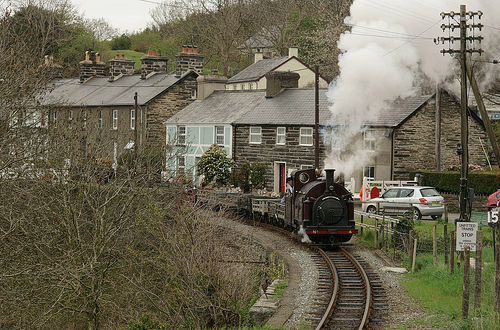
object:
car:
[361, 177, 449, 225]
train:
[237, 157, 362, 247]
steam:
[332, 1, 497, 161]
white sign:
[455, 219, 479, 255]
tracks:
[307, 246, 387, 328]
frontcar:
[283, 168, 360, 242]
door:
[268, 160, 290, 192]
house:
[168, 50, 498, 247]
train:
[178, 154, 373, 274]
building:
[235, 22, 362, 61]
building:
[221, 47, 328, 93]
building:
[9, 43, 218, 178]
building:
[160, 69, 272, 190]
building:
[230, 67, 491, 194]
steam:
[323, 0, 492, 181]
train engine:
[284, 165, 358, 248]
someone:
[283, 174, 299, 231]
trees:
[15, 53, 195, 310]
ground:
[381, 209, 474, 264]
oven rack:
[299, 177, 357, 208]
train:
[186, 167, 356, 248]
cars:
[215, 173, 324, 226]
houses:
[23, 55, 487, 212]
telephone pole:
[439, 5, 482, 227]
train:
[45, 166, 357, 253]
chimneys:
[39, 49, 104, 76]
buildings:
[30, 21, 488, 276]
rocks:
[294, 253, 319, 309]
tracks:
[249, 216, 385, 326]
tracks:
[180, 192, 381, 326]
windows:
[249, 127, 313, 146]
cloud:
[325, 8, 474, 192]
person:
[283, 177, 295, 202]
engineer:
[284, 177, 296, 201]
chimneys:
[140, 43, 202, 77]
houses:
[37, 42, 200, 164]